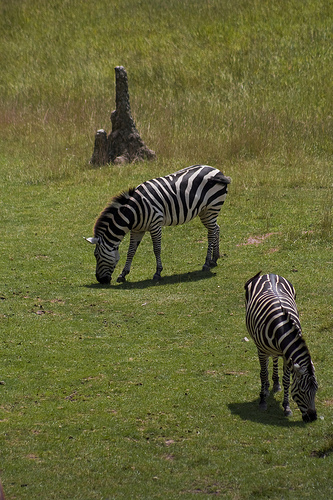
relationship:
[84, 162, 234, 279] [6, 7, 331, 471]
animal in a savannah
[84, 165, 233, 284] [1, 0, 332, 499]
zebra eating grass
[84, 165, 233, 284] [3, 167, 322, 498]
zebra in grass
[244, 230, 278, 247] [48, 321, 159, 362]
dirt in grass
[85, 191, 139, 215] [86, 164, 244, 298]
mane on zebra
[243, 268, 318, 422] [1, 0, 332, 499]
zebra grazing grass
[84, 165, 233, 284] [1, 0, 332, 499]
zebra grazing grass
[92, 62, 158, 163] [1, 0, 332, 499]
rock structure in grass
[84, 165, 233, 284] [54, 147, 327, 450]
zebra on grass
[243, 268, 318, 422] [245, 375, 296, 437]
zebra has zebra hooves